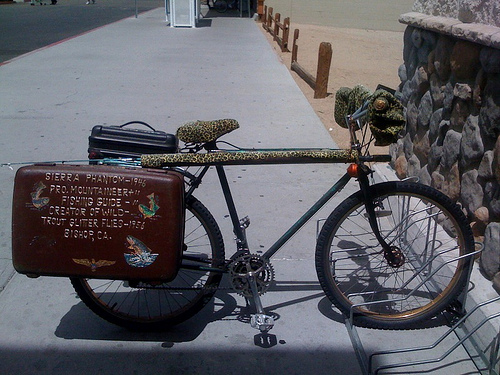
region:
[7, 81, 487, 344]
bicycle with printed seat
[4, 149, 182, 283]
suitcase on side of bicycle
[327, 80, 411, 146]
handlebars of bicycle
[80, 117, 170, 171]
black case on other side of bicycle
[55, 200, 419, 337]
shadow of bicycle on pavement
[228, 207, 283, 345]
pedals of the bicycle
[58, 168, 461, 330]
tires of the bicycle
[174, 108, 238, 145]
patterned seat of bicycle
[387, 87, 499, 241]
rock wall in front of bicycle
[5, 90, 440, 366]
sidewalk bicycle is on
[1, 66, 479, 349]
A bike in the foreground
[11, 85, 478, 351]
A side view of a bike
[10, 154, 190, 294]
A case is on the back of the bike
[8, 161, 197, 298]
A brown colored case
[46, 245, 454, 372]
Bike is casting a shadow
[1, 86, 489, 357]
Bike is parked near a stone wall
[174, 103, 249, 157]
Seat of the bike is leopard printed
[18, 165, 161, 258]
Case has wording on the side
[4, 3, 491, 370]
Photo was taken in the daytime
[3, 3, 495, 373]
Photo was taken outdoors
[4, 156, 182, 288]
suitcase on bike is brown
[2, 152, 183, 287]
suitcase has much writing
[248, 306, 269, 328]
metal pedal of bik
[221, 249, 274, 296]
gear area of bike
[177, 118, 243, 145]
seat of bike with design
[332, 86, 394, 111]
handle bars of bike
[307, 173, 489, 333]
front wheel of bike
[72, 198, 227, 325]
back wheel of bike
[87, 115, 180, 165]
black bag behind bike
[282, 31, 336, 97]
wooden pole behind bike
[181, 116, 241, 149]
cheetah print bike seat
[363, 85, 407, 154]
cheetah print bike handles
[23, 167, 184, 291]
brown carrying case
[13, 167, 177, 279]
brown carrying case with writing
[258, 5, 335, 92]
wooden fence missing posts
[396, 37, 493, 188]
stone wall along beach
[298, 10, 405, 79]
golden brown sand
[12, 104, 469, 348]
pike is parked at a bike rack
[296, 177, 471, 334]
wheel has gold interior rim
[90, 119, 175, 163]
small black carrier attached to bike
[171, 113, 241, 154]
leopard print bike seat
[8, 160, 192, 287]
maroon suitcase with stickers and writing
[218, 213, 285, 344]
two bike pedals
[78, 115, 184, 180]
black suitcase on side of bike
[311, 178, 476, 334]
front tire of a bike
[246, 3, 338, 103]
broken wooden post fence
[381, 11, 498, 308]
gray and brown stone wall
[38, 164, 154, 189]
the words "Sierra Phantom" - 1946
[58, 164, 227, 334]
rear tire of the bicycle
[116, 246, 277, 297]
chain and gears of the bicycle